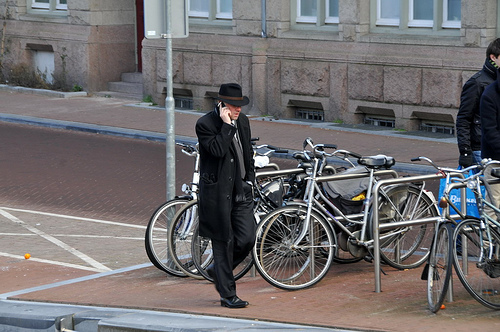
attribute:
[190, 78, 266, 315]
man — talking, walking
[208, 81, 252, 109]
hat — black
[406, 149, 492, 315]
bicycles — parked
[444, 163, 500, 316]
bicycles — parked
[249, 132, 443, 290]
bicycles — parked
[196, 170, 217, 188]
gloves — black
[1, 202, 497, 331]
floor — brown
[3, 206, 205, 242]
stripes — white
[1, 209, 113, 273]
stripes — white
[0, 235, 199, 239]
stripes — white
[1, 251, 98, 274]
stripes — white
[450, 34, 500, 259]
man — walking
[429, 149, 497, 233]
bag — blue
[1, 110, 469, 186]
curb — blue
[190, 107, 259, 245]
coat — black, long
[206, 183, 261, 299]
pants — black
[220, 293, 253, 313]
shoe — black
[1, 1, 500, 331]
picture — daytime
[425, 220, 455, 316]
wheel — turned